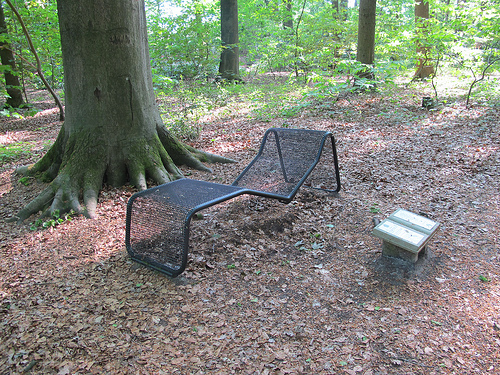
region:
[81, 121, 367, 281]
oddly shaped metal bench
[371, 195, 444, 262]
small concrete statue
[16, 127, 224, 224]
exposed tree roots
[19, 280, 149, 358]
bark and leaves in the dirt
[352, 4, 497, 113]
bright green vegetation and trees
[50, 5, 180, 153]
brown and green tree trunk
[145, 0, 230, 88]
tree with vibrant leaves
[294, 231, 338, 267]
leaf on the ground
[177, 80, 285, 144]
sunbeams on the ground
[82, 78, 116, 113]
notch in the tree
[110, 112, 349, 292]
bent metal frame in the woods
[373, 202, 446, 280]
square in the dead leaves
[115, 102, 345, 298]
black metal frame in the forest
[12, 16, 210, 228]
tree trunk with many roots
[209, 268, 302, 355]
dead laves on the forest floor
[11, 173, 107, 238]
reaching roots of a tree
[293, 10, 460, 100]
tree trunks and greenery in the forest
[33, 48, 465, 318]
debris in a forest clearing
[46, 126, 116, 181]
moss growing on a tree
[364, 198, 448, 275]
tree stump with cement on top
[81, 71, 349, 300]
the chair is black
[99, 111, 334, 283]
the chair is made of metal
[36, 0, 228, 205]
tree log is brown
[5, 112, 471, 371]
ground is covered in leaves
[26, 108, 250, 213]
moss growing on bottom of tree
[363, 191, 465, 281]
brown and silver object in front of chair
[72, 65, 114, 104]
tree has hole in it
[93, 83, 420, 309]
the chair is empty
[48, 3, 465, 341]
chair is in forest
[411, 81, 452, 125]
black object on ground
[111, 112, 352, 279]
a curved bench near a tree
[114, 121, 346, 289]
bench is black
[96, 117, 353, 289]
the curved bench is metal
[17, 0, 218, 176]
a trunk of a tree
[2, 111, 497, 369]
floor is cover with trees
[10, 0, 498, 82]
green vegetation with green leaves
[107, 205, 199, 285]
leg of bench is wide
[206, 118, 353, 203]
right side of bench is bend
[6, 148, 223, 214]
the roots of tree can be seen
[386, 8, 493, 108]
small trees are growing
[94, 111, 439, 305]
Bench on the ground.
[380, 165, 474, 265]
Sign on the ground.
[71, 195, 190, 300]
Leaves on the ground.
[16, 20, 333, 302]
Tree on the ground.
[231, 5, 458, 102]
Green leaves on the trees.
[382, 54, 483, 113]
Branches on the trees.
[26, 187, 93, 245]
Roots of the tree.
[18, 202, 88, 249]
Green shrub on ground.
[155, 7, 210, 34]
Sky in between trees.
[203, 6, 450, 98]
Trunks of the trees.